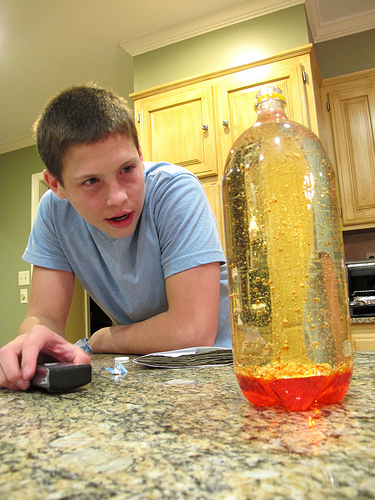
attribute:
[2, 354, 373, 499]
surface — black, white, shiny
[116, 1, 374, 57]
molding — crown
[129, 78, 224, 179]
door — brown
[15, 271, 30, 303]
sockets — white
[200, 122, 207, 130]
knobs — round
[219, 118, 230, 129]
knobs — round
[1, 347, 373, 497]
table — designed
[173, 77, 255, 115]
cabinets — wooden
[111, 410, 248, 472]
counter top — marble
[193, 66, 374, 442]
bottle — plastic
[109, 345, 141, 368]
tablet — white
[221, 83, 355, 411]
bottle — plastic, two liter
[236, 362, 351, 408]
liquid — red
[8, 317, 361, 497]
table top — granite